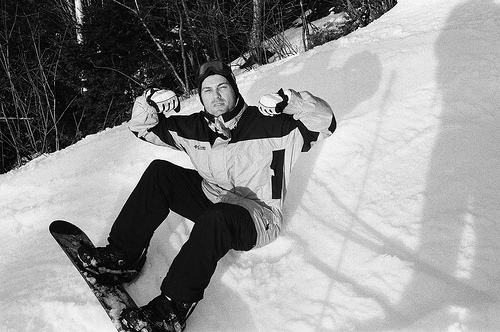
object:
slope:
[339, 33, 490, 328]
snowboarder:
[47, 220, 188, 329]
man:
[76, 61, 337, 332]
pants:
[104, 158, 270, 298]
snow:
[373, 134, 499, 241]